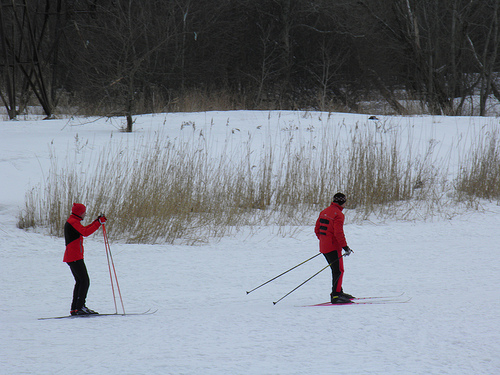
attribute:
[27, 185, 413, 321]
skiers — moving, skiing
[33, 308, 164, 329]
skis — cross country, red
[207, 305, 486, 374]
snow — white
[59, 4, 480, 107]
trees — dead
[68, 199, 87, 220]
hat — red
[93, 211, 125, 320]
poles — red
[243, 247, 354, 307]
poles — black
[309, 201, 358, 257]
jacket — red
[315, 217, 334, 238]
stripes — black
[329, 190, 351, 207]
hat — black, tan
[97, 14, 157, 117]
tree — brown, large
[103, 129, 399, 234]
grass — tall, brown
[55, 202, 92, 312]
suit — red, black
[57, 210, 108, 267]
coat — red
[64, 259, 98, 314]
pants — black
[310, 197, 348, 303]
outfit — red